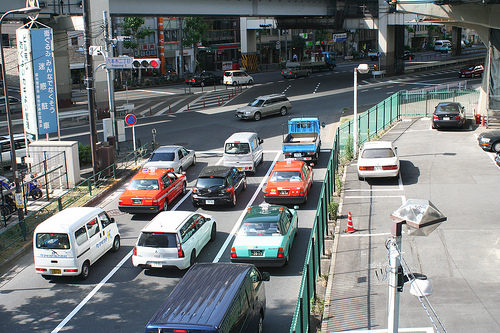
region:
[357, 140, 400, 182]
Parked white car on street.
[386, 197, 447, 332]
Light pole on street.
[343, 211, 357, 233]
Orange - and - white striped traffic cone.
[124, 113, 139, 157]
Traffic sign on city street.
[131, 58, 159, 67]
Traffic lights on city street.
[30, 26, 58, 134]
Blue sign with white lettering.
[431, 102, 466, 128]
Parked black car on street.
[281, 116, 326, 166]
Blue pickup truck on city street.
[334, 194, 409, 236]
Empty parking space Traffic on street.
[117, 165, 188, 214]
Orange car on city street.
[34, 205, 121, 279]
White van in traffic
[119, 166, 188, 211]
Red taxi in traffic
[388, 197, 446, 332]
Top of a streetlight on a road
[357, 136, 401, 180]
Shiny white car parked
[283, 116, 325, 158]
Blue truck with empty truck bed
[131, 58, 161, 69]
Sideways traffic light signaling to stop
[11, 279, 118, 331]
Shade from a tree on a road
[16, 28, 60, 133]
White and blue sign with writing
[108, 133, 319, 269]
Multiple cars stuck in traffic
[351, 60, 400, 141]
Street light surrounded by green fence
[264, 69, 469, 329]
this is a fence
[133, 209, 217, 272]
this is a white car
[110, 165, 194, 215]
a small red car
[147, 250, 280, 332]
a long black van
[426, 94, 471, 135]
a small black car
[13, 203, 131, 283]
a little white van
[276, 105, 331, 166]
a light blue truck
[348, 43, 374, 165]
this is a street light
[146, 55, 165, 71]
this is a red light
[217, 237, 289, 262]
these are tail lights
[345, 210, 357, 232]
orange and white traffic cone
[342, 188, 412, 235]
empty designated parking space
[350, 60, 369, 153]
silver and white tall street lamp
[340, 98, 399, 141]
tall green fencing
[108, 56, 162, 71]
horizontal traffic light currently on red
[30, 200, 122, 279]
large white passenger van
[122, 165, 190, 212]
brightly colored orange and white taxi cab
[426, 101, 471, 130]
parked black passenger sedan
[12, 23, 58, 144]
large blue and white sign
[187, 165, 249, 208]
modern looking black sedan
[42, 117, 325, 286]
cars driving down street lanes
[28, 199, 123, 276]
white van on street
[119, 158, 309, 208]
two red cabs on raod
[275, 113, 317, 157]
blue truck on road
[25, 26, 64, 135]
blue and white cube shaped sign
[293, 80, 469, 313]
green fence along roadway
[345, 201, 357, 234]
orange and white safety cone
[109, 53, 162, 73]
white traffic signal with red ligth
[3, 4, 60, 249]
street lamp and pole with sign attached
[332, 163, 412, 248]
white lines painted in parking lot